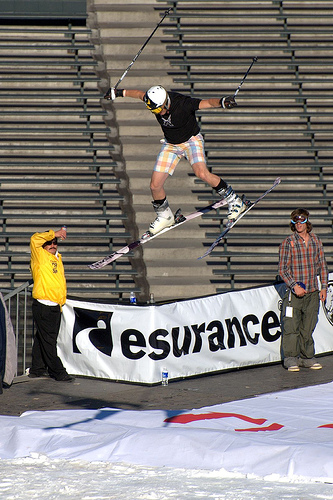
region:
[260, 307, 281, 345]
The letter is black.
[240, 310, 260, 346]
The letter is black.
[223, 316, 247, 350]
The letter is black.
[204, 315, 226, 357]
The letter is black.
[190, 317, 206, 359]
The letter is black.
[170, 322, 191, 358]
The letter is black.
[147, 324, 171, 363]
The letter is black.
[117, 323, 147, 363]
The letter is black.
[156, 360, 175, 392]
The water bottle is sitting on the ground.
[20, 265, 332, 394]
The banner is black and white.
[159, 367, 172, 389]
A small, clear water bottle by the white sign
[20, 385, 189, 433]
The black shadow of the skier on the ground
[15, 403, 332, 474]
A large white tarp beneath the skier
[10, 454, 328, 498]
Fluffy white snow along the ground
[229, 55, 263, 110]
A black and white ski pole in the man's hand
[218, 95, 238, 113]
A black glove on the man's hand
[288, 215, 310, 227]
Blue goggle on the bystander's face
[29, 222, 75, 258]
The man is shielding his eyes from the sun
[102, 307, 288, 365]
Large black writing on the white sign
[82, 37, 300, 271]
The skier is high in the air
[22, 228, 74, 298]
the jacket is yellow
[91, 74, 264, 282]
man suspended in the air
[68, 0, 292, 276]
Skier in air doing a trick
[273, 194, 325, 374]
Skier watching event and probably participating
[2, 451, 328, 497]
Snow on ground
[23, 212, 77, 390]
Man in yellow jacket watching event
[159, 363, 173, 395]
Water bottle on ground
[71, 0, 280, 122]
Two black ski poles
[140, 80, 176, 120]
White helmet and yellow goggles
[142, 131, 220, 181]
Pastel colored plaid shorts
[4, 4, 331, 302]
Empty bleachers in stands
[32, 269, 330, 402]
esurance advertising banner